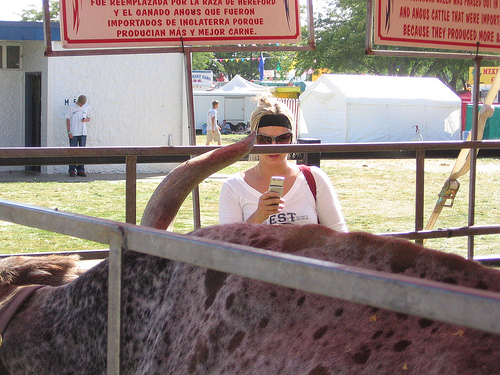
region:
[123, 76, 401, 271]
A person is using their cell phone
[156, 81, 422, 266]
A person is sending a text message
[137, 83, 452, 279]
A person is wearing dark sunglasses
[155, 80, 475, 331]
A person is standing by a fence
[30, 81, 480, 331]
A person is close to some livestock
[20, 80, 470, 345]
A person is out in the daytime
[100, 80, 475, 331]
A person is waiting for somebody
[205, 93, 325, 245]
woman is holding a phone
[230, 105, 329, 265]
woman is holding a phone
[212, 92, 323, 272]
woman is holding a phone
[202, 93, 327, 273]
woman is holding a phone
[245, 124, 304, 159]
woman is wearing sunglasses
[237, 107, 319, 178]
woman is wearing sunglasses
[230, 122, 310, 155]
woman is wearing sunglasses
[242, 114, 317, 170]
woman is wearing sunglasses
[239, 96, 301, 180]
head of a person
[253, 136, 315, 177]
mouth of a person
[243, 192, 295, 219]
finger of a person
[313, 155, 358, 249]
arm of a person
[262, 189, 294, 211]
fingers of a person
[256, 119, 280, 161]
eye of a person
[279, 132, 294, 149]
eye of a person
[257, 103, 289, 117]
hair of a person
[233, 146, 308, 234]
person using a phone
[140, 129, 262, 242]
the horn of a bull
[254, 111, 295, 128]
a black headband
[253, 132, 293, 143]
a black pair of sunglasses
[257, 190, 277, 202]
a long finger on a hand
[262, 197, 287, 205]
a long finger on a hand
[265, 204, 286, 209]
a long finger on a hand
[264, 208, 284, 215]
a long finger on a hand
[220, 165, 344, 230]
a white and black shirt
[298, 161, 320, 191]
a red strap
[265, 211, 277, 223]
a black letter E on the shirt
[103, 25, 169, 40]
Red lettering on a white sign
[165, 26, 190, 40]
Red lettering on a white sign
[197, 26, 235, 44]
Red lettering on a white sign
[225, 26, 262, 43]
Red lettering on a white sign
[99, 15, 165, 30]
Red lettering on a white sign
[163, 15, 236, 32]
Red lettering on a white sign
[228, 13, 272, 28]
Red lettering on a white sign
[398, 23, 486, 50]
Red lettering on a white sign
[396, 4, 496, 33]
Red lettering on a white sign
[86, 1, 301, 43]
White and red sign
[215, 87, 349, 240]
a girl holding a cell phone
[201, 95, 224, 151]
a boy is walking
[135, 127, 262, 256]
the horn is big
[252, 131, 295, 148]
girl is wearing sunglasses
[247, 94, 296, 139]
the girl's hair is blonde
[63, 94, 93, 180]
a man standing near a white wall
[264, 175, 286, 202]
the cell phone is silver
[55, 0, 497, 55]
red and white signs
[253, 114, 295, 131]
the girl is wearing a black headband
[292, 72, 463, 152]
a large white tent behind the girl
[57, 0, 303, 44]
white sign with red lettering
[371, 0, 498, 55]
white sign with red lettering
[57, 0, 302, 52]
white sign with red border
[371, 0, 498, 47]
white sign with red border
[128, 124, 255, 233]
long smooth horn of an animal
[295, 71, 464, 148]
white tarp over a small building